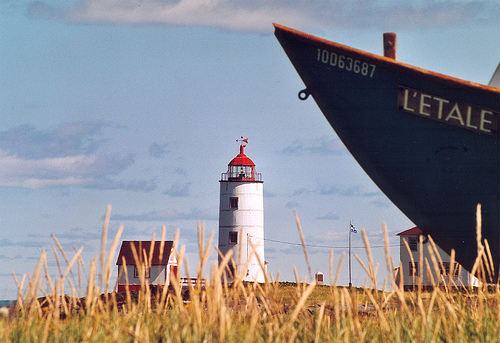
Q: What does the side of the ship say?
A: L'ETALE.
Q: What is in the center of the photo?
A: A lighthouse.